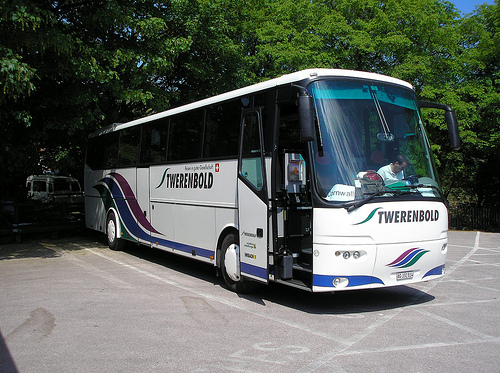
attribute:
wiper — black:
[336, 99, 396, 210]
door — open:
[249, 101, 330, 294]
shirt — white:
[353, 134, 407, 199]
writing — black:
[164, 170, 216, 191]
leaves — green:
[9, 6, 55, 108]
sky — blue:
[54, 0, 484, 95]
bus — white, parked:
[77, 64, 464, 300]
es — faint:
[227, 335, 310, 366]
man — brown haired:
[377, 153, 411, 186]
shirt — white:
[376, 161, 404, 183]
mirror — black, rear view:
[416, 97, 465, 155]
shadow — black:
[121, 247, 437, 317]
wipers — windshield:
[367, 86, 394, 137]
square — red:
[212, 160, 222, 172]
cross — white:
[214, 163, 219, 169]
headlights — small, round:
[331, 240, 450, 258]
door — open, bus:
[233, 101, 275, 291]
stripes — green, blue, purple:
[91, 169, 162, 244]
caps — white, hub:
[223, 241, 242, 280]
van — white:
[20, 170, 84, 205]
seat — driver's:
[364, 144, 389, 174]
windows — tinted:
[84, 90, 283, 173]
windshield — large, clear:
[306, 78, 446, 203]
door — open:
[235, 85, 313, 285]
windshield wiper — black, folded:
[344, 189, 420, 212]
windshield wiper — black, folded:
[390, 183, 445, 195]